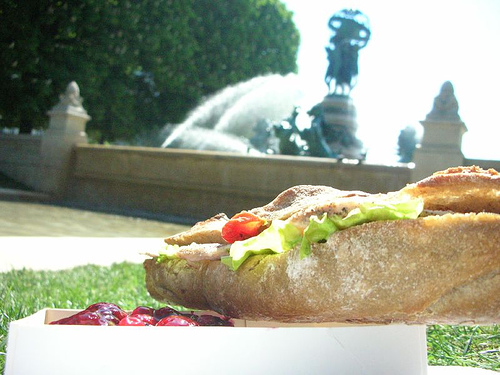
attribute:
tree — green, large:
[1, 0, 298, 149]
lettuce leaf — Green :
[221, 193, 424, 273]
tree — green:
[6, 0, 293, 119]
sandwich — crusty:
[130, 150, 499, 345]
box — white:
[26, 324, 81, 370]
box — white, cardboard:
[12, 315, 436, 374]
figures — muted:
[316, 4, 388, 165]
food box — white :
[4, 303, 429, 374]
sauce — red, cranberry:
[47, 276, 229, 343]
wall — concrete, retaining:
[6, 125, 497, 233]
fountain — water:
[278, 0, 378, 167]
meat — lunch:
[176, 240, 230, 263]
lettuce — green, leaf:
[218, 195, 427, 272]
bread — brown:
[329, 228, 470, 321]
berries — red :
[46, 300, 233, 327]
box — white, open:
[7, 303, 428, 373]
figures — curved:
[225, 42, 429, 172]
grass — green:
[2, 264, 169, 307]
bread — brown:
[105, 175, 493, 320]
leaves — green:
[6, 1, 299, 121]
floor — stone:
[2, 178, 202, 238]